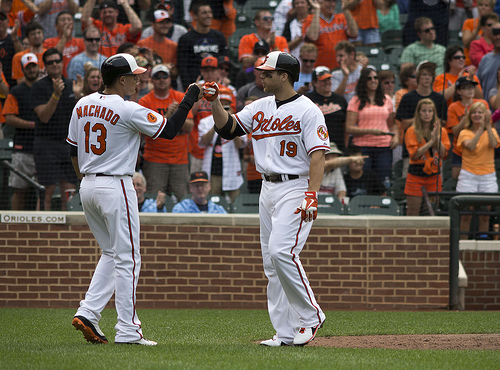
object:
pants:
[72, 170, 149, 346]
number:
[90, 122, 110, 157]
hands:
[200, 80, 222, 103]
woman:
[454, 99, 499, 242]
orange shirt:
[401, 122, 452, 175]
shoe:
[257, 332, 295, 347]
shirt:
[400, 42, 451, 79]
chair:
[344, 193, 401, 219]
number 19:
[277, 138, 298, 158]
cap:
[253, 49, 301, 84]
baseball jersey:
[211, 92, 332, 176]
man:
[171, 168, 229, 215]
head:
[259, 48, 300, 94]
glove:
[293, 190, 318, 224]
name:
[73, 102, 121, 125]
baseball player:
[63, 52, 210, 347]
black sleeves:
[126, 83, 202, 141]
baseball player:
[201, 48, 331, 350]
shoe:
[69, 312, 109, 345]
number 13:
[81, 119, 108, 157]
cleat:
[75, 320, 83, 326]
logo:
[315, 123, 330, 141]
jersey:
[65, 90, 170, 177]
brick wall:
[326, 226, 351, 238]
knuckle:
[198, 83, 205, 88]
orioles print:
[248, 109, 303, 141]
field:
[0, 303, 499, 368]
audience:
[403, 96, 453, 216]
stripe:
[119, 178, 143, 341]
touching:
[64, 46, 334, 350]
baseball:
[0, 50, 499, 369]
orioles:
[247, 108, 302, 141]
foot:
[292, 315, 327, 348]